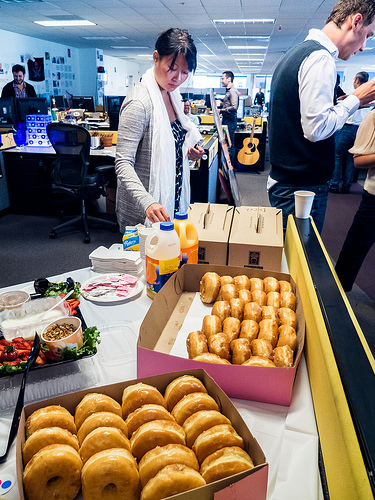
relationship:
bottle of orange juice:
[142, 222, 182, 300] [175, 221, 196, 244]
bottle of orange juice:
[170, 208, 198, 269] [175, 221, 196, 244]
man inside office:
[265, 0, 374, 243] [0, 0, 374, 499]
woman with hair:
[115, 26, 204, 233] [154, 26, 197, 76]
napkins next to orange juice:
[89, 246, 141, 273] [143, 210, 198, 294]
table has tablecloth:
[62, 264, 131, 351] [0, 246, 325, 497]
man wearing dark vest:
[267, 0, 373, 236] [269, 41, 337, 187]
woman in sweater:
[115, 26, 204, 233] [113, 82, 158, 234]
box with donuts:
[13, 367, 270, 499] [23, 373, 253, 496]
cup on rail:
[291, 185, 317, 220] [289, 213, 348, 398]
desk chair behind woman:
[27, 106, 121, 243] [112, 26, 207, 235]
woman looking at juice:
[112, 26, 207, 235] [149, 184, 215, 275]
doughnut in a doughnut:
[22, 443, 79, 499] [22, 426, 79, 463]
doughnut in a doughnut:
[22, 443, 79, 499] [25, 404, 75, 430]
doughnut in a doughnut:
[22, 443, 79, 499] [81, 446, 138, 499]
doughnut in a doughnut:
[22, 443, 79, 499] [78, 424, 130, 463]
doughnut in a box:
[22, 443, 79, 499] [13, 367, 270, 499]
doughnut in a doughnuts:
[22, 440, 87, 498] [183, 328, 209, 354]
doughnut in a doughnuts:
[22, 440, 87, 498] [200, 311, 221, 338]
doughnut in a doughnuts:
[22, 440, 87, 498] [211, 299, 230, 322]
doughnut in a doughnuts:
[22, 440, 87, 498] [217, 282, 238, 302]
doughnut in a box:
[22, 440, 87, 498] [135, 259, 306, 409]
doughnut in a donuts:
[22, 440, 87, 498] [165, 372, 206, 410]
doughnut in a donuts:
[22, 440, 87, 498] [119, 379, 167, 419]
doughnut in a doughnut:
[22, 440, 87, 498] [22, 440, 87, 498]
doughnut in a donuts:
[22, 440, 87, 498] [199, 445, 255, 481]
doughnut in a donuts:
[22, 440, 87, 498] [135, 462, 205, 498]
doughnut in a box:
[22, 440, 87, 498] [13, 367, 270, 499]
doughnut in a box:
[22, 440, 87, 498] [129, 339, 306, 419]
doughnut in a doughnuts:
[22, 440, 87, 498] [188, 330, 207, 353]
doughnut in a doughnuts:
[22, 440, 87, 498] [19, 443, 81, 498]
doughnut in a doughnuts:
[22, 440, 87, 498] [85, 451, 139, 499]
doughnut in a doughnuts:
[22, 440, 87, 498] [202, 312, 221, 334]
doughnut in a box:
[22, 440, 87, 498] [126, 259, 311, 432]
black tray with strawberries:
[0, 271, 96, 385] [6, 339, 38, 365]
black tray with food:
[0, 271, 96, 385] [6, 289, 77, 358]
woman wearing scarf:
[115, 26, 204, 233] [137, 65, 201, 227]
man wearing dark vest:
[265, 0, 374, 243] [267, 36, 341, 192]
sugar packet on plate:
[119, 273, 141, 284] [80, 271, 142, 304]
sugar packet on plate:
[81, 286, 94, 289] [80, 271, 142, 304]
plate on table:
[80, 271, 142, 304] [1, 254, 326, 498]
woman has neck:
[115, 26, 204, 233] [142, 73, 172, 100]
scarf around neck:
[140, 64, 203, 218] [142, 73, 172, 100]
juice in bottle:
[144, 228, 181, 303] [142, 218, 179, 300]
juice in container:
[172, 219, 199, 265] [170, 210, 201, 265]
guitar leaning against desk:
[223, 116, 271, 173] [231, 119, 268, 175]